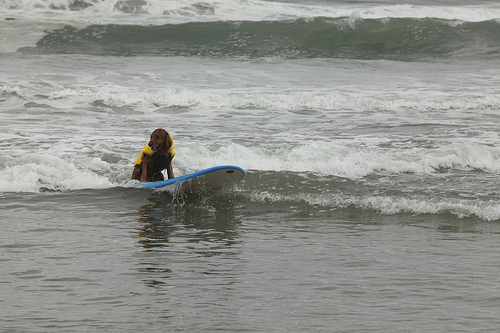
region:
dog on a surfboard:
[122, 124, 247, 194]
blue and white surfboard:
[136, 159, 248, 201]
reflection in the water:
[132, 206, 222, 243]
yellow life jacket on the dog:
[127, 131, 183, 184]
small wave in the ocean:
[7, 108, 491, 230]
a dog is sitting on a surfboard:
[120, 106, 242, 206]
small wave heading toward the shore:
[17, 0, 490, 63]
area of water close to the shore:
[0, 192, 492, 327]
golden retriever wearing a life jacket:
[127, 106, 174, 188]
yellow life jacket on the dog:
[132, 134, 174, 168]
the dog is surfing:
[116, 110, 241, 201]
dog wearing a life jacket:
[129, 136, 182, 170]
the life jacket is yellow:
[129, 136, 187, 171]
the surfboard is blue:
[128, 153, 257, 200]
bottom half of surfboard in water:
[116, 158, 253, 213]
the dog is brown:
[110, 116, 188, 196]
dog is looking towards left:
[122, 118, 192, 193]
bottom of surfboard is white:
[149, 156, 246, 209]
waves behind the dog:
[1, 0, 494, 227]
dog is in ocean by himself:
[113, 109, 255, 209]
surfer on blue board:
[96, 110, 228, 192]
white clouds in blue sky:
[26, 16, 63, 47]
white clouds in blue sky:
[403, 16, 450, 66]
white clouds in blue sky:
[300, 4, 337, 34]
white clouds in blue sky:
[333, 4, 373, 51]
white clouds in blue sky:
[199, 0, 249, 60]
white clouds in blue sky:
[260, 11, 291, 52]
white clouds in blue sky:
[137, 10, 197, 47]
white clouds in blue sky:
[170, 14, 205, 56]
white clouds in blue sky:
[33, 7, 84, 49]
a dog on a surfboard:
[132, 130, 177, 175]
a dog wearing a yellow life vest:
[131, 126, 174, 178]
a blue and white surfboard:
[147, 165, 248, 192]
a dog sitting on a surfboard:
[125, 129, 251, 192]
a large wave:
[28, 14, 494, 85]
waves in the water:
[243, 67, 485, 218]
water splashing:
[151, 179, 208, 200]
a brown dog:
[129, 125, 178, 182]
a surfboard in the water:
[130, 165, 249, 192]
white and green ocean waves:
[271, 39, 326, 97]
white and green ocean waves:
[380, 98, 425, 146]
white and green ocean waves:
[294, 218, 332, 253]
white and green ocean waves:
[200, 295, 257, 330]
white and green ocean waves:
[215, 45, 269, 73]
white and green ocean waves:
[318, 63, 425, 125]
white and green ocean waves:
[54, 68, 88, 122]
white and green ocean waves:
[44, 156, 89, 230]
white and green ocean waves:
[331, 149, 396, 204]